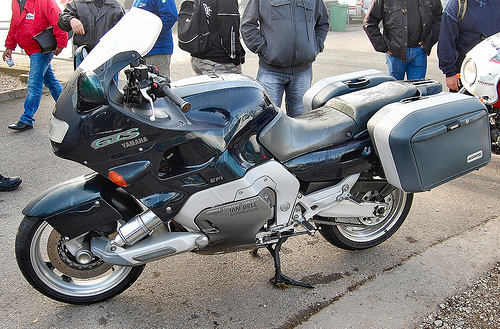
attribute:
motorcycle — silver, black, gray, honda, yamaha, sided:
[16, 5, 493, 304]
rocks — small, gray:
[407, 297, 472, 329]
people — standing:
[2, 1, 499, 130]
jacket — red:
[6, 1, 69, 50]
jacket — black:
[362, 1, 444, 62]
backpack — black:
[178, 1, 214, 54]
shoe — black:
[0, 173, 21, 192]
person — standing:
[242, 1, 332, 116]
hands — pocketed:
[383, 42, 429, 57]